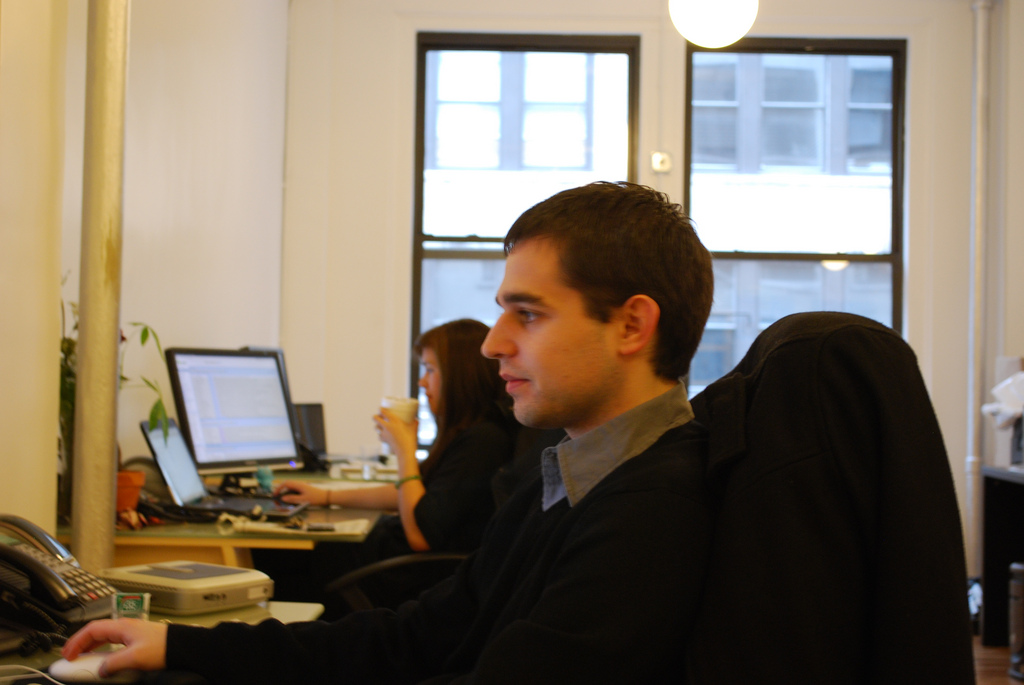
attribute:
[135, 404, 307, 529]
laptop — small, black